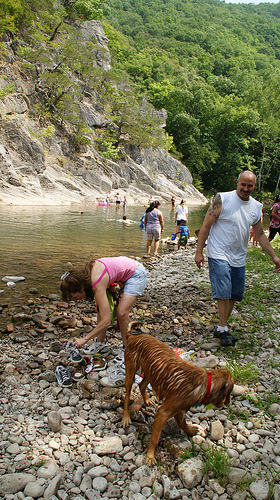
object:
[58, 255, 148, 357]
woman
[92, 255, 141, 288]
shirt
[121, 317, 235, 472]
dog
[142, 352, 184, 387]
fur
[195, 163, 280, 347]
man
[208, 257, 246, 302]
jeans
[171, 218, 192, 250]
child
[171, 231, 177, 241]
bucket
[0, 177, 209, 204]
bottom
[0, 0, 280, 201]
mountian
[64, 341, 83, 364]
shoe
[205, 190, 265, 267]
shirt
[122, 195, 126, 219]
people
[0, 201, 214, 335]
water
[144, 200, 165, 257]
lady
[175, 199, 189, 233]
girl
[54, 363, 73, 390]
shoes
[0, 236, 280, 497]
ground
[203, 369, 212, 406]
collar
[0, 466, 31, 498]
rock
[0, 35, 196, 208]
side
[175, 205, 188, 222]
shirt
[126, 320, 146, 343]
tail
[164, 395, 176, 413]
brown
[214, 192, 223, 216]
sleeves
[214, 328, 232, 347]
shoes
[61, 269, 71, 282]
clip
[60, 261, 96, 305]
hair